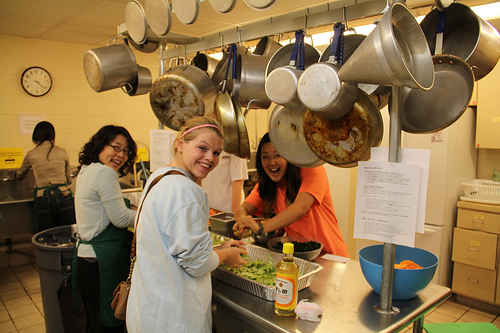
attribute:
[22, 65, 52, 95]
clock — white, black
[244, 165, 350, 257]
shirt — orange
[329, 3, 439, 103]
pan — hanging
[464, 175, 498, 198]
dish strainer — white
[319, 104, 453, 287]
papers — white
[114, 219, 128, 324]
purse — brown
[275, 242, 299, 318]
bottle — oil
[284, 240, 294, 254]
cap — yellow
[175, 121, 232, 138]
headband — pink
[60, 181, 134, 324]
apron — green